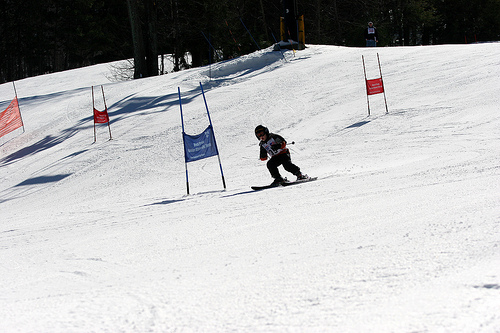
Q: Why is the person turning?
A: To avoid hitting the flag.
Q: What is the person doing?
A: Skiing.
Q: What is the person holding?
A: Ski Poles.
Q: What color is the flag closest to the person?
A: Blue.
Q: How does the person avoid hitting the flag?
A: Turning.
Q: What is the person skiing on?
A: Snow.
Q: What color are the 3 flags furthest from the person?
A: Red.